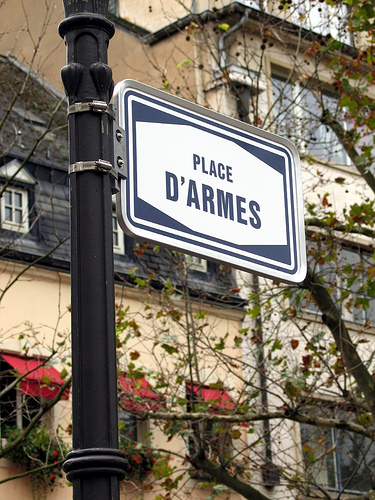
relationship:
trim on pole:
[57, 443, 133, 483] [58, 0, 127, 500]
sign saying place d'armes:
[111, 80, 306, 283] [153, 134, 267, 236]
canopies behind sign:
[0, 348, 245, 418] [110, 63, 342, 298]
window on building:
[300, 209, 363, 318] [151, 19, 373, 325]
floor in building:
[253, 191, 364, 330] [151, 19, 373, 325]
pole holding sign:
[58, 12, 128, 425] [111, 80, 309, 283]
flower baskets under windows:
[21, 440, 161, 482] [4, 377, 57, 435]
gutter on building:
[231, 82, 280, 490] [1, 0, 373, 499]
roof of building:
[0, 53, 250, 312] [1, 1, 233, 497]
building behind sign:
[1, 1, 233, 497] [111, 80, 309, 283]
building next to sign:
[217, 2, 373, 499] [111, 80, 306, 283]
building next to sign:
[1, 1, 250, 497] [111, 80, 306, 283]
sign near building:
[111, 80, 306, 283] [1, 0, 373, 499]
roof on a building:
[0, 53, 250, 312] [1, 1, 233, 497]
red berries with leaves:
[47, 449, 160, 479] [13, 427, 175, 487]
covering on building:
[0, 350, 70, 400] [1, 0, 373, 499]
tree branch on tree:
[114, 388, 374, 441] [299, 31, 373, 478]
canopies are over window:
[15, 348, 258, 413] [4, 397, 19, 422]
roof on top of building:
[0, 53, 250, 312] [3, 162, 341, 494]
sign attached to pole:
[111, 80, 309, 283] [56, 0, 117, 436]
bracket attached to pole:
[68, 159, 115, 174] [56, 0, 117, 436]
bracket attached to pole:
[65, 99, 113, 117] [56, 0, 117, 436]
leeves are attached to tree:
[310, 200, 372, 232] [249, 52, 367, 133]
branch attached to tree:
[280, 409, 349, 434] [249, 52, 367, 133]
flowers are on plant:
[289, 339, 299, 349] [308, 267, 372, 387]